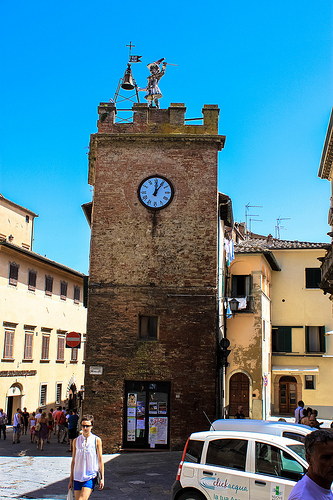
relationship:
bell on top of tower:
[120, 63, 135, 91] [98, 81, 221, 134]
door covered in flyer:
[148, 380, 169, 449] [127, 393, 136, 406]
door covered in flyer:
[148, 380, 169, 449] [128, 406, 135, 415]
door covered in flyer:
[148, 380, 169, 449] [127, 416, 135, 431]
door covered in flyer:
[148, 380, 169, 449] [127, 432, 134, 441]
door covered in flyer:
[122, 380, 146, 448] [158, 401, 167, 414]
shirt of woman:
[73, 431, 98, 481] [67, 413, 105, 500]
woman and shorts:
[67, 413, 105, 500] [73, 476, 91, 490]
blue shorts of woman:
[72, 476, 95, 490] [67, 413, 105, 500]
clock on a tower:
[136, 172, 175, 211] [80, 96, 227, 453]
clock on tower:
[137, 174, 175, 211] [82, 39, 226, 452]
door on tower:
[123, 380, 147, 448] [80, 96, 227, 453]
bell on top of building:
[119, 62, 137, 90] [77, 102, 234, 456]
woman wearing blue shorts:
[67, 413, 105, 500] [72, 470, 95, 492]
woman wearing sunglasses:
[67, 413, 105, 500] [145, 64, 163, 72]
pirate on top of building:
[136, 57, 178, 108] [78, 101, 235, 450]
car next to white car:
[170, 410, 309, 500] [207, 411, 316, 441]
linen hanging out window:
[226, 297, 247, 312] [230, 274, 248, 302]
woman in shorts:
[67, 413, 105, 500] [71, 476, 95, 491]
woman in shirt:
[67, 413, 105, 500] [73, 431, 98, 481]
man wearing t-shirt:
[289, 430, 331, 498] [286, 474, 330, 499]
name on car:
[201, 468, 251, 497] [170, 430, 309, 497]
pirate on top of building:
[140, 57, 165, 105] [78, 101, 235, 450]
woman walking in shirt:
[67, 413, 105, 500] [73, 432, 98, 483]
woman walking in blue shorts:
[67, 413, 105, 500] [69, 473, 98, 490]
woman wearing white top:
[67, 413, 105, 500] [69, 433, 99, 481]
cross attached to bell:
[122, 39, 136, 51] [118, 60, 137, 92]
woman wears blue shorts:
[66, 410, 112, 497] [66, 473, 99, 497]